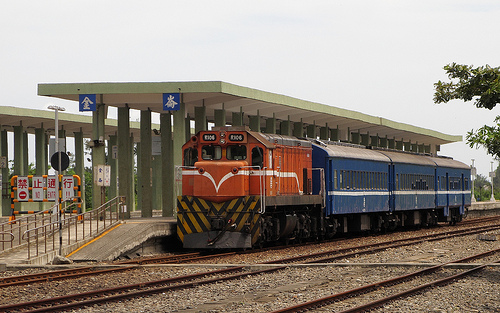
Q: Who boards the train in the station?
A: People, children, pets.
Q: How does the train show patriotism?
A: By being painted with red, white and blue.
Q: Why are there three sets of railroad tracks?
A: There are probably three railroads.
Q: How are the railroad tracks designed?
A: Vertically.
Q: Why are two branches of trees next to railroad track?
A: The railroad track is probably near a forest or open space.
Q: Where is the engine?
A: On the train.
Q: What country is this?
A: An Asian country.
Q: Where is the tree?
A: Alongside tracks.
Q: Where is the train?
A: On the tracks.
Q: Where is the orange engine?
A: On the train.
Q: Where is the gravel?
A: Under the tracks.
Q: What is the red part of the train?
A: Engine.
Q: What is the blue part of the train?
A: The cars.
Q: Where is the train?
A: At the station.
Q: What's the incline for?
A: Handicap accessibility.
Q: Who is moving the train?
A: Conductor.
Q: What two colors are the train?
A: Blue and red.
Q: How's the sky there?
A: Overcast.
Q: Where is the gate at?
A: Left side.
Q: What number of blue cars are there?
A: Three.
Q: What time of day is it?
A: Afternoon.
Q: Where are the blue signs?
A: Hanging from roof.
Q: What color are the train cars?
A: Blue.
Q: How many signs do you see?
A: 7.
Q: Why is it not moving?
A: Its picking up riders.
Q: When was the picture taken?
A: Daytime.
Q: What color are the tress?
A: Green.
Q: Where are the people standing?
A: No people.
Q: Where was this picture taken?
A: At a train stop.